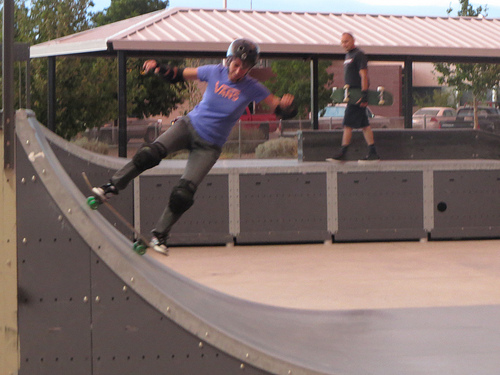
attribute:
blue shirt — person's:
[187, 62, 269, 145]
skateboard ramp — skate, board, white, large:
[14, 107, 498, 370]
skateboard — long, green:
[80, 169, 163, 256]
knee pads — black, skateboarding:
[133, 142, 199, 215]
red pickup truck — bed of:
[233, 107, 284, 145]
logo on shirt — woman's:
[214, 80, 240, 104]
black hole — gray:
[436, 201, 446, 212]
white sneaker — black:
[149, 226, 168, 249]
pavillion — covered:
[36, 18, 482, 180]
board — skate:
[74, 163, 187, 264]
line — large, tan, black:
[230, 165, 244, 239]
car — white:
[417, 91, 451, 131]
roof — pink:
[71, 14, 223, 61]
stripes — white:
[280, 16, 312, 46]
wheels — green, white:
[128, 229, 146, 263]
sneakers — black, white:
[82, 175, 179, 265]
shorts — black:
[339, 87, 389, 137]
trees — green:
[59, 67, 103, 128]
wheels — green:
[78, 180, 160, 268]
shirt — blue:
[175, 47, 253, 141]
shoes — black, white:
[81, 163, 181, 262]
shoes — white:
[93, 178, 189, 268]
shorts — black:
[328, 90, 385, 140]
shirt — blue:
[194, 56, 249, 161]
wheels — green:
[78, 185, 172, 275]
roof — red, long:
[29, 7, 486, 59]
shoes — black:
[150, 233, 170, 253]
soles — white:
[150, 242, 167, 255]